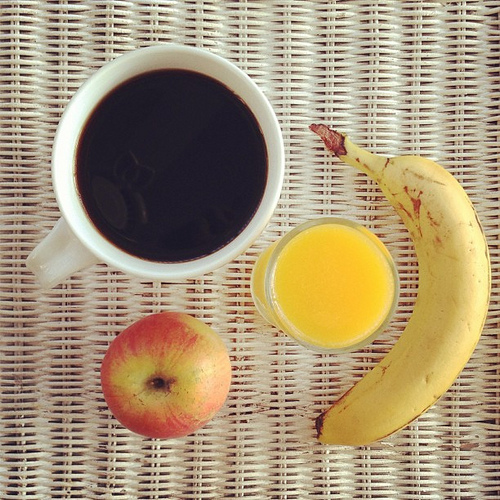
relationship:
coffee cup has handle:
[27, 42, 288, 304] [25, 215, 94, 297]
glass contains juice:
[249, 215, 406, 355] [275, 225, 392, 348]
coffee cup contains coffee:
[27, 42, 288, 304] [75, 69, 271, 263]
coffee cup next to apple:
[27, 42, 288, 304] [98, 310, 237, 440]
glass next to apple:
[249, 215, 406, 355] [98, 310, 237, 440]